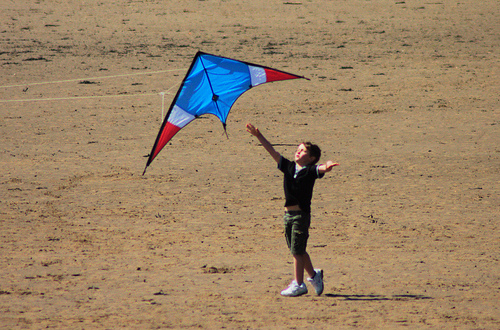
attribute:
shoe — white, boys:
[279, 279, 308, 299]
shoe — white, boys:
[306, 265, 331, 297]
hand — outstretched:
[211, 107, 295, 162]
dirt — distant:
[332, 0, 432, 76]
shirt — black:
[275, 153, 322, 214]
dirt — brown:
[84, 216, 217, 307]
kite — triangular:
[124, 29, 318, 182]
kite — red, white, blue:
[119, 37, 309, 173]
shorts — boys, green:
[269, 209, 318, 256]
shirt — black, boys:
[274, 152, 327, 218]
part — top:
[183, 43, 223, 78]